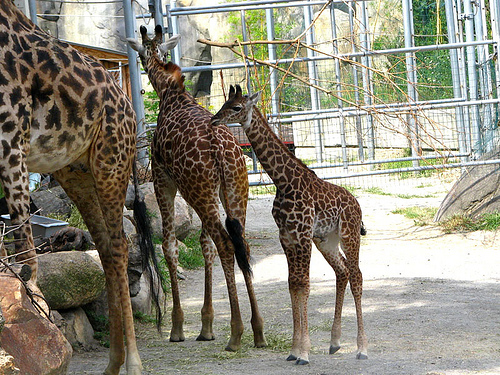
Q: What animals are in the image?
A: Giraffes.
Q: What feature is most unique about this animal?
A: Their necks.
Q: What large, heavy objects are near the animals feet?
A: Rocks.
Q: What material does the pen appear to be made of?
A: Metal.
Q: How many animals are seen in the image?
A: Three.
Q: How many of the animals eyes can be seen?
A: One.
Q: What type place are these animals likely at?
A: A zoo.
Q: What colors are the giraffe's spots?
A: Brown.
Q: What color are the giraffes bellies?
A: White.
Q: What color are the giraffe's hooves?
A: Black.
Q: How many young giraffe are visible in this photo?
A: One.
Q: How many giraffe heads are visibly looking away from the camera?
A: One.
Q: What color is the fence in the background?
A: Silver.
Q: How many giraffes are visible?
A: Three.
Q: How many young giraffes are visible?
A: Two.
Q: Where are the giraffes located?
A: Enclosures.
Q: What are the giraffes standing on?
A: Dirt ground.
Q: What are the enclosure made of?
A: Metal.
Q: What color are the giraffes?
A: Brown and tan.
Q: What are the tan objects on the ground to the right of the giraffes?
A: Rocks.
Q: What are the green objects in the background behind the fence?
A: Trees and foliage.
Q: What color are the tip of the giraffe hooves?
A: Black.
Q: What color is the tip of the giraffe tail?
A: Dark brown.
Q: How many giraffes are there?
A: 3.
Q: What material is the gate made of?
A: Steel.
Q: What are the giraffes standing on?
A: Grass.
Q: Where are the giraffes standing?
A: Inside of a gate.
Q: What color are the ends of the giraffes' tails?
A: Black.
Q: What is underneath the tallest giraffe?
A: Rocks.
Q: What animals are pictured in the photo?
A: Giraffes.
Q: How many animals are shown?
A: Three.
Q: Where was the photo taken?
A: A zoo.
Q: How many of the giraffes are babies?
A: One.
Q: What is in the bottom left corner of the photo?
A: A rock.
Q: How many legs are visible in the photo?
A: Eleven.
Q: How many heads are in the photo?
A: Two.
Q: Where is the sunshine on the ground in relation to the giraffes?
A: Behind and to the right.